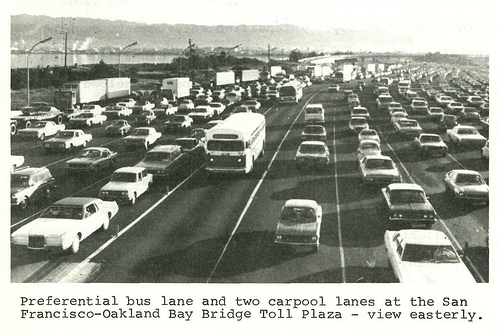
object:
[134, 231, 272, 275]
shadow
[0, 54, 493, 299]
ground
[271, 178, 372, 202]
shadow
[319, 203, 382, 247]
shadow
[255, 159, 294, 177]
shadow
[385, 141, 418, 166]
shadow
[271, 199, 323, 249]
car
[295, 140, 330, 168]
car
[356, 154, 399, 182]
car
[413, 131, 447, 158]
car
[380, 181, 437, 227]
car